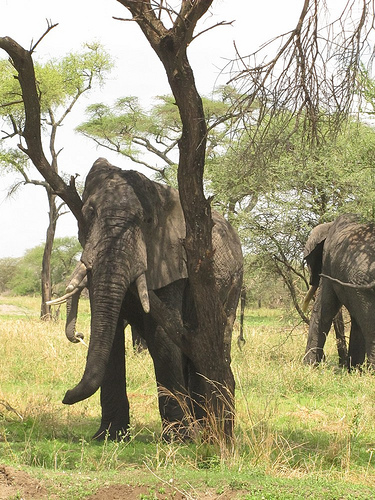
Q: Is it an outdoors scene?
A: Yes, it is outdoors.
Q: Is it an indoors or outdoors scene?
A: It is outdoors.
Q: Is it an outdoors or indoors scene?
A: It is outdoors.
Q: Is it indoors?
A: No, it is outdoors.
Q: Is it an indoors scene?
A: No, it is outdoors.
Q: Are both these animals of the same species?
A: Yes, all the animals are elephants.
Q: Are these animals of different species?
A: No, all the animals are elephants.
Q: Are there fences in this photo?
A: No, there are no fences.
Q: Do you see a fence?
A: No, there are no fences.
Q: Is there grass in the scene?
A: Yes, there is grass.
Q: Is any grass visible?
A: Yes, there is grass.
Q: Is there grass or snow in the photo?
A: Yes, there is grass.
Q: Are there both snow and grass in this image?
A: No, there is grass but no snow.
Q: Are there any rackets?
A: No, there are no rackets.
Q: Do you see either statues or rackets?
A: No, there are no rackets or statues.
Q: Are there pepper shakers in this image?
A: No, there are no pepper shakers.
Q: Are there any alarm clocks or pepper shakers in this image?
A: No, there are no pepper shakers or alarm clocks.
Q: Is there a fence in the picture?
A: No, there are no fences.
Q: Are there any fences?
A: No, there are no fences.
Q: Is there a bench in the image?
A: No, there are no benches.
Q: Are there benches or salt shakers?
A: No, there are no benches or salt shakers.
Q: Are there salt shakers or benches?
A: No, there are no benches or salt shakers.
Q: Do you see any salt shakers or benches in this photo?
A: No, there are no benches or salt shakers.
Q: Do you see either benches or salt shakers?
A: No, there are no benches or salt shakers.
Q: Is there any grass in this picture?
A: Yes, there is grass.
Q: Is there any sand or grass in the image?
A: Yes, there is grass.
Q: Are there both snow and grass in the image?
A: No, there is grass but no snow.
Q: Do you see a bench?
A: No, there are no benches.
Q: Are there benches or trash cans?
A: No, there are no benches or trash cans.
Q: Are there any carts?
A: No, there are no carts.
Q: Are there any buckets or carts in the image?
A: No, there are no carts or buckets.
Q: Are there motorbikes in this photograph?
A: No, there are no motorbikes.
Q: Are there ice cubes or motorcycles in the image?
A: No, there are no motorcycles or ice cubes.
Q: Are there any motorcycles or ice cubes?
A: No, there are no motorcycles or ice cubes.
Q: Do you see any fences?
A: No, there are no fences.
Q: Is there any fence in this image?
A: No, there are no fences.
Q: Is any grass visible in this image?
A: Yes, there is grass.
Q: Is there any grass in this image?
A: Yes, there is grass.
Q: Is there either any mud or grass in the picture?
A: Yes, there is grass.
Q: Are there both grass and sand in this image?
A: No, there is grass but no sand.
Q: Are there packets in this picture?
A: No, there are no packets.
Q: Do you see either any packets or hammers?
A: No, there are no packets or hammers.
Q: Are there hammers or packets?
A: No, there are no packets or hammers.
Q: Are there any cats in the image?
A: No, there are no cats.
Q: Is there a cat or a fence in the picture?
A: No, there are no cats or fences.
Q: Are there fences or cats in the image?
A: No, there are no cats or fences.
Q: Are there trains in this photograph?
A: Yes, there is a train.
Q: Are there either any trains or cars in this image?
A: Yes, there is a train.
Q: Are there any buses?
A: No, there are no buses.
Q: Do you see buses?
A: No, there are no buses.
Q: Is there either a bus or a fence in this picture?
A: No, there are no buses or fences.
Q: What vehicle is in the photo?
A: The vehicle is a train.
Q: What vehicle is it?
A: The vehicle is a train.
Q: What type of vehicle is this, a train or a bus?
A: This is a train.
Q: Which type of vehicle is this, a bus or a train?
A: This is a train.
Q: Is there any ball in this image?
A: No, there are no balls.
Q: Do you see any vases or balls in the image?
A: No, there are no balls or vases.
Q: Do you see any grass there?
A: Yes, there is grass.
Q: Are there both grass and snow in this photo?
A: No, there is grass but no snow.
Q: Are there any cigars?
A: No, there are no cigars.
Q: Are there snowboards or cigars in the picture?
A: No, there are no cigars or snowboards.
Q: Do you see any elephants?
A: Yes, there is an elephant.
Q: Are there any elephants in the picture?
A: Yes, there is an elephant.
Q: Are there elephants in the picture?
A: Yes, there is an elephant.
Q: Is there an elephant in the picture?
A: Yes, there is an elephant.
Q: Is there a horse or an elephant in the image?
A: Yes, there is an elephant.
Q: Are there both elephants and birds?
A: No, there is an elephant but no birds.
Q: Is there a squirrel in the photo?
A: No, there are no squirrels.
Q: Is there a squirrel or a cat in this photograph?
A: No, there are no squirrels or cats.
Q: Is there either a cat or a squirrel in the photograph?
A: No, there are no squirrels or cats.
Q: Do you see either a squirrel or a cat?
A: No, there are no squirrels or cats.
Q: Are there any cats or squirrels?
A: No, there are no squirrels or cats.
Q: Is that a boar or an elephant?
A: That is an elephant.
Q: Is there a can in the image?
A: No, there are no cans.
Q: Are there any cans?
A: No, there are no cans.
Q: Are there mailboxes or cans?
A: No, there are no cans or mailboxes.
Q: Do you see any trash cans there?
A: No, there are no trash cans.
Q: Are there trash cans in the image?
A: No, there are no trash cans.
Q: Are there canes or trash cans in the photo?
A: No, there are no trash cans or canes.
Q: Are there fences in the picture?
A: No, there are no fences.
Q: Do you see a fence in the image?
A: No, there are no fences.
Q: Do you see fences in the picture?
A: No, there are no fences.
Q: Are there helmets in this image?
A: No, there are no helmets.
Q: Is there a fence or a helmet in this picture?
A: No, there are no helmets or fences.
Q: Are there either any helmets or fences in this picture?
A: No, there are no helmets or fences.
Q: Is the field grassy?
A: Yes, the field is grassy.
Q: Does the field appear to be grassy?
A: Yes, the field is grassy.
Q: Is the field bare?
A: No, the field is grassy.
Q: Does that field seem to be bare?
A: No, the field is grassy.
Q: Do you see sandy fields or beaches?
A: No, there is a field but it is grassy.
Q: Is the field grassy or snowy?
A: The field is grassy.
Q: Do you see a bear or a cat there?
A: No, there are no cats or bears.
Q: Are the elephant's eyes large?
A: No, the eyes are small.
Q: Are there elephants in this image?
A: Yes, there is an elephant.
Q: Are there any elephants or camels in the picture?
A: Yes, there is an elephant.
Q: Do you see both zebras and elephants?
A: No, there is an elephant but no zebras.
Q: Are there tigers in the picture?
A: No, there are no tigers.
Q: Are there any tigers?
A: No, there are no tigers.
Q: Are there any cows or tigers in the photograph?
A: No, there are no tigers or cows.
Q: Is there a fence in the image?
A: No, there are no fences.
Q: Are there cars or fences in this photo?
A: No, there are no fences or cars.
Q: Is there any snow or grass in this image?
A: Yes, there is grass.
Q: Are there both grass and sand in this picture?
A: No, there is grass but no sand.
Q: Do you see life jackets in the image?
A: No, there are no life jackets.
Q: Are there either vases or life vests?
A: No, there are no life vests or vases.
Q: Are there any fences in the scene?
A: No, there are no fences.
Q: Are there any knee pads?
A: No, there are no knee pads.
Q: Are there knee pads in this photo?
A: No, there are no knee pads.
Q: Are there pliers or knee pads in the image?
A: No, there are no knee pads or pliers.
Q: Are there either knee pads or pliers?
A: No, there are no knee pads or pliers.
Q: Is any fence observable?
A: No, there are no fences.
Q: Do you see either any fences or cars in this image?
A: No, there are no fences or cars.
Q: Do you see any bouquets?
A: No, there are no bouquets.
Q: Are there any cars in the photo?
A: No, there are no cars.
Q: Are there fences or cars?
A: No, there are no cars or fences.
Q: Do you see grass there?
A: Yes, there is grass.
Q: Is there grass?
A: Yes, there is grass.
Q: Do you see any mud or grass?
A: Yes, there is grass.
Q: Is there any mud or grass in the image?
A: Yes, there is grass.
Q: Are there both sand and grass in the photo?
A: No, there is grass but no sand.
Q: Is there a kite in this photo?
A: No, there are no kites.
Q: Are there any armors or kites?
A: No, there are no kites or armors.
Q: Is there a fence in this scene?
A: No, there are no fences.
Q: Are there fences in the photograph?
A: No, there are no fences.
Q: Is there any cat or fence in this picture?
A: No, there are no fences or cats.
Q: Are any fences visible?
A: No, there are no fences.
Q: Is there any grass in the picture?
A: Yes, there is grass.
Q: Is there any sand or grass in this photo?
A: Yes, there is grass.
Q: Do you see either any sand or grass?
A: Yes, there is grass.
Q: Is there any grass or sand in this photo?
A: Yes, there is grass.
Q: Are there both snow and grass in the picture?
A: No, there is grass but no snow.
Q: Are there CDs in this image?
A: No, there are no cds.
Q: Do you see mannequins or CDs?
A: No, there are no CDs or mannequins.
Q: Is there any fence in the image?
A: No, there are no fences.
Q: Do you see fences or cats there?
A: No, there are no fences or cats.